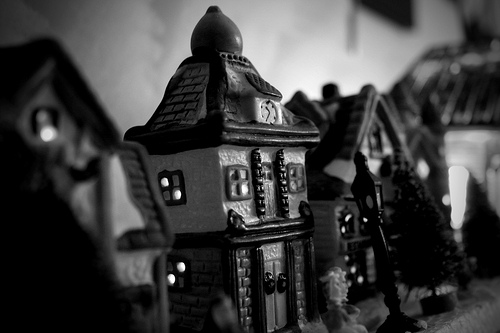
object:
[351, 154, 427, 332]
lamp post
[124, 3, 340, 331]
house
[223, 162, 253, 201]
windows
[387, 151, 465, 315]
tree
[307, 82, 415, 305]
house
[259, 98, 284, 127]
clock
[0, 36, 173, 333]
houses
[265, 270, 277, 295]
handles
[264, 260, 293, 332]
door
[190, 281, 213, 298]
brick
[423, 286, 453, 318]
planter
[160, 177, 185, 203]
light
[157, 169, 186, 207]
window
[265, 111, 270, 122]
clock hands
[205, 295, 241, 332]
doll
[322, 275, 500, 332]
ground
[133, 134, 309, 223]
top floor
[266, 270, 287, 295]
design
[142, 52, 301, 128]
roof